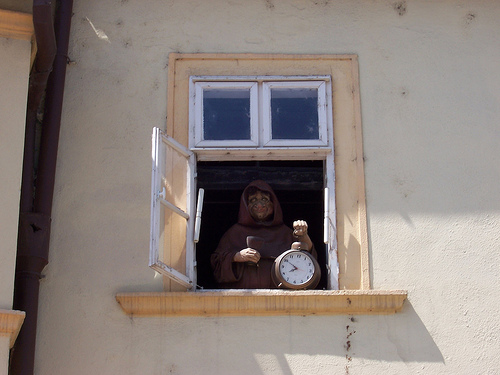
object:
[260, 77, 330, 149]
window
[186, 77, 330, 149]
frame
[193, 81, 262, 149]
window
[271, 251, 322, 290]
clock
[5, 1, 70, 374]
beam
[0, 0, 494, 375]
stucco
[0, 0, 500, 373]
building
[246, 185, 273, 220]
face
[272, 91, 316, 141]
glass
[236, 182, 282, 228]
hood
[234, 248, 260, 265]
hand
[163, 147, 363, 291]
frame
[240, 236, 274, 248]
cap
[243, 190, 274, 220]
mask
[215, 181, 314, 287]
person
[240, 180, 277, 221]
head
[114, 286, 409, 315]
windowsill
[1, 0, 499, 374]
wall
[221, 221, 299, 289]
robe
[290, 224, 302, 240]
handle